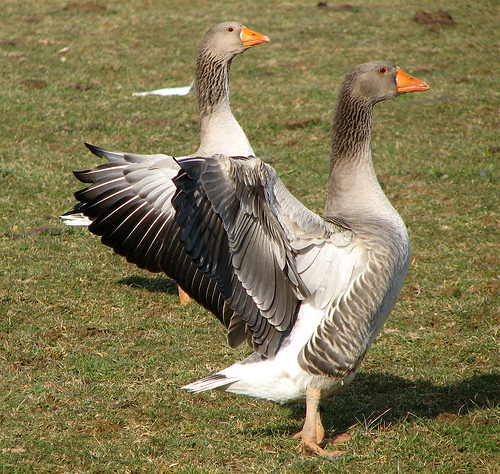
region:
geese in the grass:
[67, 13, 442, 471]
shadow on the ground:
[358, 364, 487, 433]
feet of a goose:
[286, 387, 351, 466]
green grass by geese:
[29, 269, 129, 444]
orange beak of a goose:
[391, 57, 431, 102]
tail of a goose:
[169, 364, 235, 414]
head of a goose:
[198, 12, 273, 61]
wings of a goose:
[180, 147, 316, 348]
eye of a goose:
[220, 15, 237, 40]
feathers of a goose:
[89, 159, 146, 243]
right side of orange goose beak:
[391, 59, 433, 96]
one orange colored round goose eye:
[378, 64, 388, 75]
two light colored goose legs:
[293, 384, 355, 460]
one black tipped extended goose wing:
[66, 143, 325, 358]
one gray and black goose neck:
[326, 90, 377, 178]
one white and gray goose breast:
[361, 198, 411, 294]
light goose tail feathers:
[169, 365, 258, 399]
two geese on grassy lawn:
[67, 19, 453, 465]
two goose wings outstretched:
[69, 137, 344, 368]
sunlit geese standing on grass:
[25, 19, 466, 459]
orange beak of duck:
[385, 65, 423, 103]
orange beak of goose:
[244, 21, 274, 46]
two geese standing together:
[97, 18, 449, 465]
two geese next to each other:
[40, 3, 444, 463]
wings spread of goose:
[162, 143, 293, 337]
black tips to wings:
[144, 172, 238, 289]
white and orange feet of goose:
[277, 389, 338, 471]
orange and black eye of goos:
[374, 65, 396, 80]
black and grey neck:
[197, 51, 229, 108]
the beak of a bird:
[401, 60, 431, 102]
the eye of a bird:
[377, 63, 389, 77]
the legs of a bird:
[296, 382, 355, 462]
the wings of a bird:
[171, 153, 328, 328]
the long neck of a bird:
[325, 86, 376, 212]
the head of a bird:
[339, 37, 433, 120]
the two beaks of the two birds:
[183, 23, 433, 108]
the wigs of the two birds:
[57, 133, 303, 303]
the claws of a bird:
[298, 438, 348, 461]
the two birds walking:
[88, 20, 423, 472]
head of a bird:
[343, 45, 443, 133]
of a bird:
[173, 15, 273, 77]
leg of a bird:
[286, 371, 348, 459]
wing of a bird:
[49, 129, 294, 324]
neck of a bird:
[177, 58, 262, 143]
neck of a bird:
[297, 112, 401, 223]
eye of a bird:
[217, 15, 252, 42]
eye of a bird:
[373, 52, 417, 80]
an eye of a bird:
[372, 62, 402, 83]